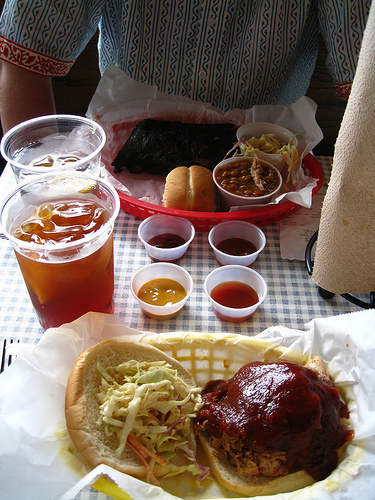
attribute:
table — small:
[4, 156, 374, 368]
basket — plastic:
[92, 102, 326, 231]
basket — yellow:
[56, 334, 365, 500]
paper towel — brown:
[313, 3, 373, 295]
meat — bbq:
[112, 118, 239, 176]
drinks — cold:
[2, 114, 122, 330]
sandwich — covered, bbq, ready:
[64, 337, 355, 496]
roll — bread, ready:
[161, 163, 218, 214]